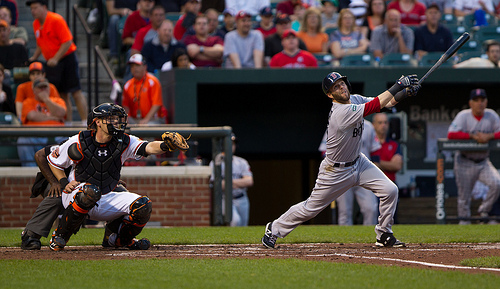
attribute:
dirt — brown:
[3, 232, 498, 270]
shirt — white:
[445, 110, 498, 163]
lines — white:
[107, 252, 331, 259]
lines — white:
[346, 244, 496, 254]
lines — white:
[335, 252, 498, 271]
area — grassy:
[21, 81, 493, 285]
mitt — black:
[157, 126, 189, 155]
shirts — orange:
[15, 15, 183, 120]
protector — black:
[74, 129, 131, 193]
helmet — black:
[317, 69, 349, 81]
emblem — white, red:
[326, 72, 338, 82]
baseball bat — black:
[407, 31, 472, 96]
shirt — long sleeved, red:
[447, 112, 485, 142]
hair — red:
[300, 16, 324, 31]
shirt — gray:
[221, 25, 265, 65]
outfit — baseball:
[444, 106, 485, 217]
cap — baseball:
[469, 83, 485, 103]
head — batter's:
[315, 60, 357, 110]